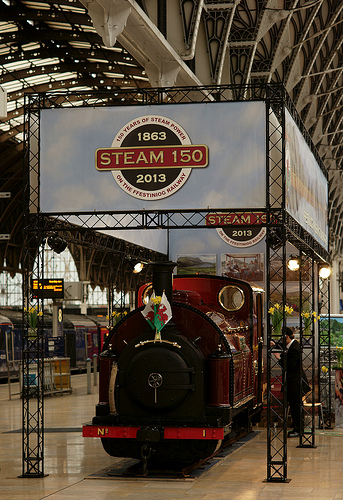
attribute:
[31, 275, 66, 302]
sign —  black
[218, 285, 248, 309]
window — circular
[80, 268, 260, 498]
train —  blue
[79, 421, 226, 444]
stripe — red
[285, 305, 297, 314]
flower — yellow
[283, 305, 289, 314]
flower — yellow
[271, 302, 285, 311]
flower — yellow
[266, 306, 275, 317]
flower — yellow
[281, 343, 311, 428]
suit — black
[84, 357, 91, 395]
pole — white and blue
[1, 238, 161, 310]
window — glass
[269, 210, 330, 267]
beams — black, metal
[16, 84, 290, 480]
engine display — steam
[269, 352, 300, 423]
shirt — black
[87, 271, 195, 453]
smokestack — black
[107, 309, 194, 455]
flowers — yellow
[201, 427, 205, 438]
i — gold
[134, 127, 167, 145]
1863 — yellow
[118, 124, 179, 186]
background — black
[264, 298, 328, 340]
flowers — yellow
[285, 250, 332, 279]
lights — white